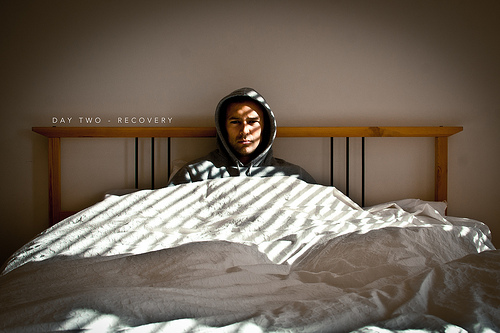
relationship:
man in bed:
[164, 85, 319, 197] [1, 119, 499, 332]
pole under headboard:
[132, 136, 144, 190] [29, 119, 466, 228]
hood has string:
[210, 86, 280, 163] [245, 160, 259, 178]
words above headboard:
[49, 114, 177, 127] [29, 119, 466, 228]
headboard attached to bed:
[29, 119, 466, 228] [1, 119, 499, 332]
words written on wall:
[49, 114, 177, 127] [0, 1, 499, 251]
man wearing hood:
[164, 85, 319, 197] [210, 86, 280, 163]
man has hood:
[164, 85, 319, 197] [210, 86, 280, 163]